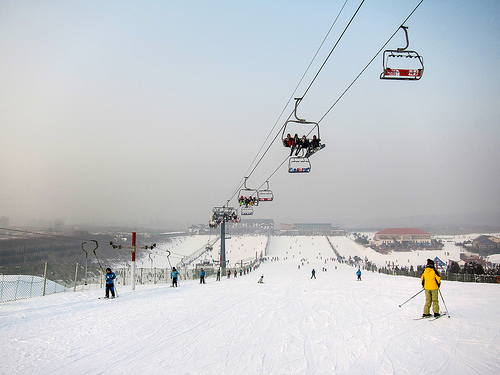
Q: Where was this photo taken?
A: At ski slopes.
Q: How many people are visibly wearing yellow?
A: One.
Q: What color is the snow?
A: White.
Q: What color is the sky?
A: Blue.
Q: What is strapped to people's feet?
A: Skis.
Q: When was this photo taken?
A: During the winter months.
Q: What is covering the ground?
A: Snow.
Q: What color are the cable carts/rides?
A: Black.